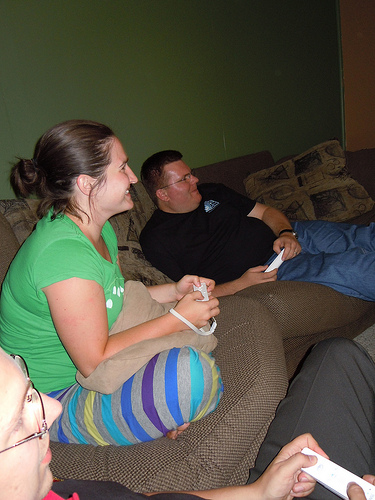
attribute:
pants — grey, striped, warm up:
[31, 342, 226, 459]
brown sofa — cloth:
[0, 144, 373, 492]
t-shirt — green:
[1, 209, 124, 393]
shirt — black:
[146, 188, 274, 276]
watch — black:
[273, 225, 298, 235]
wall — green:
[4, 3, 342, 175]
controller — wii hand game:
[189, 274, 211, 313]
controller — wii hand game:
[256, 248, 299, 282]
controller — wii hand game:
[288, 439, 374, 496]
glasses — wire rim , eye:
[0, 344, 52, 463]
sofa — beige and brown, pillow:
[246, 140, 369, 216]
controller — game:
[249, 226, 319, 307]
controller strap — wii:
[165, 302, 220, 339]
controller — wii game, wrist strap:
[235, 229, 315, 324]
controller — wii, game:
[298, 446, 374, 496]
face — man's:
[2, 349, 66, 499]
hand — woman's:
[171, 290, 220, 331]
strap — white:
[150, 307, 234, 353]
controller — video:
[189, 269, 228, 311]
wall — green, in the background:
[0, 1, 345, 199]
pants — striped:
[38, 333, 258, 447]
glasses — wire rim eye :
[158, 168, 196, 192]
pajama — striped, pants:
[19, 294, 254, 468]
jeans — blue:
[282, 221, 373, 301]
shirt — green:
[1, 206, 133, 399]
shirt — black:
[136, 186, 285, 283]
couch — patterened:
[0, 147, 360, 339]